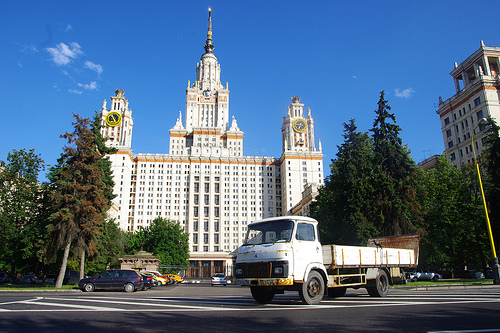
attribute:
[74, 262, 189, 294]
cars — parked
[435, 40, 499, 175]
building — tall, white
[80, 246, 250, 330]
parking lot — paved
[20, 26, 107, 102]
cloud — in the picture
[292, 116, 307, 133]
clock — large, round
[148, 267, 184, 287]
car — yellow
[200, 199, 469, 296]
truck — antique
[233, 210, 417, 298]
truck — white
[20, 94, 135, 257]
tree — brown, green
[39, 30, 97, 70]
clouds — lonely, white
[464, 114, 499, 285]
light — tall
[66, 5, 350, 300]
setting — urban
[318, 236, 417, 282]
truck bed — wooden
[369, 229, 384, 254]
bird — small, black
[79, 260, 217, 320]
cars — in the picture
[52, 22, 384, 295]
building — large, white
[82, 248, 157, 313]
car — parked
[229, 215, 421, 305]
truck — light blue, white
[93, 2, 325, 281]
building — white, tall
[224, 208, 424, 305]
truck — old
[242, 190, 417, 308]
vehicle — dark blue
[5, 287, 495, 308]
lines — white, painted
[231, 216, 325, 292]
cab — white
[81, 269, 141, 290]
car — black